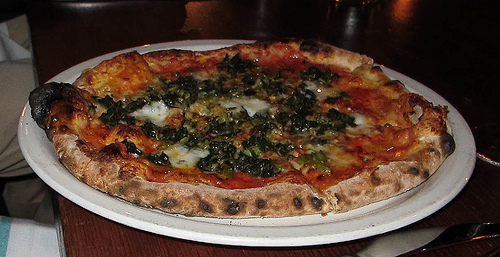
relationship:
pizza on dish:
[25, 38, 460, 223] [14, 34, 482, 253]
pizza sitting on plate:
[25, 38, 460, 223] [14, 34, 482, 253]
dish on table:
[14, 34, 482, 253] [17, 0, 498, 257]